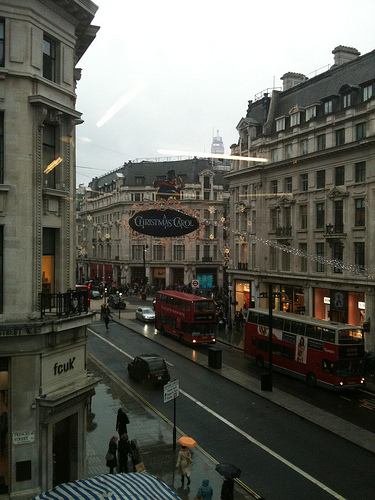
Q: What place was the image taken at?
A: It was taken at the street.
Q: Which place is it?
A: It is a street.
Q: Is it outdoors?
A: Yes, it is outdoors.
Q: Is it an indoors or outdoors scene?
A: It is outdoors.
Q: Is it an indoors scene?
A: No, it is outdoors.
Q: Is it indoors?
A: No, it is outdoors.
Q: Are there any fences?
A: No, there are no fences.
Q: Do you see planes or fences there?
A: No, there are no fences or planes.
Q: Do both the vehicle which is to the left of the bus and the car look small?
A: Yes, both the vehicle and the car are small.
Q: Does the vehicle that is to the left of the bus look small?
A: Yes, the vehicle is small.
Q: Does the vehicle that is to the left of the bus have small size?
A: Yes, the vehicle is small.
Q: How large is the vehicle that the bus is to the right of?
A: The vehicle is small.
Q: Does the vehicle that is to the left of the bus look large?
A: No, the vehicle is small.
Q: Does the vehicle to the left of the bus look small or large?
A: The vehicle is small.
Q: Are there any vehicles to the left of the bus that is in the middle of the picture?
A: Yes, there is a vehicle to the left of the bus.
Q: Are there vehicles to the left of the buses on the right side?
A: Yes, there is a vehicle to the left of the buses.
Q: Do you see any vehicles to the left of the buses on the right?
A: Yes, there is a vehicle to the left of the buses.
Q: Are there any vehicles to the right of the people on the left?
A: Yes, there is a vehicle to the right of the people.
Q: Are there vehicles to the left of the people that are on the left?
A: No, the vehicle is to the right of the people.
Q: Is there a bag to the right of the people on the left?
A: No, there is a vehicle to the right of the people.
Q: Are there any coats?
A: Yes, there is a coat.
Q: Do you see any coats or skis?
A: Yes, there is a coat.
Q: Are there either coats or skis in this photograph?
A: Yes, there is a coat.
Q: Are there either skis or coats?
A: Yes, there is a coat.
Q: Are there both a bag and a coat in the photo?
A: No, there is a coat but no bags.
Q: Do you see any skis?
A: No, there are no skis.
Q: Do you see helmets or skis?
A: No, there are no skis or helmets.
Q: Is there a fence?
A: No, there are no fences.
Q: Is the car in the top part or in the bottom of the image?
A: The car is in the bottom of the image.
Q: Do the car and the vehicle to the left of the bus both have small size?
A: Yes, both the car and the vehicle are small.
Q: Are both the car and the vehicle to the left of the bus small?
A: Yes, both the car and the vehicle are small.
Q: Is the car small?
A: Yes, the car is small.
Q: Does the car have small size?
A: Yes, the car is small.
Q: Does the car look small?
A: Yes, the car is small.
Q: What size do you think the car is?
A: The car is small.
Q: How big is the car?
A: The car is small.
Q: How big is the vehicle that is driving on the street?
A: The car is small.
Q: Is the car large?
A: No, the car is small.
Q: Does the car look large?
A: No, the car is small.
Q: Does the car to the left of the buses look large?
A: No, the car is small.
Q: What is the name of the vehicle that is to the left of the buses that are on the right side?
A: The vehicle is a car.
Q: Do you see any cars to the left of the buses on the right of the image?
A: Yes, there is a car to the left of the buses.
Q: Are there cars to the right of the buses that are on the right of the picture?
A: No, the car is to the left of the buses.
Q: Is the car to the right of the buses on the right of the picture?
A: No, the car is to the left of the buses.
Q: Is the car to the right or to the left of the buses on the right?
A: The car is to the left of the buses.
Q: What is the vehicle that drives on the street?
A: The vehicle is a car.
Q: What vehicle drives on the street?
A: The vehicle is a car.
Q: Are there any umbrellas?
A: Yes, there is an umbrella.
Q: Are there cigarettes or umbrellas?
A: Yes, there is an umbrella.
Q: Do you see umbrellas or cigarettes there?
A: Yes, there is an umbrella.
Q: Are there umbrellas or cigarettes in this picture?
A: Yes, there is an umbrella.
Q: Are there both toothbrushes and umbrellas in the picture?
A: No, there is an umbrella but no toothbrushes.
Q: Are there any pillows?
A: No, there are no pillows.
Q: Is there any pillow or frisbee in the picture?
A: No, there are no pillows or frisbees.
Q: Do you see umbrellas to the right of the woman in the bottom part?
A: Yes, there is an umbrella to the right of the woman.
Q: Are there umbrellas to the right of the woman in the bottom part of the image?
A: Yes, there is an umbrella to the right of the woman.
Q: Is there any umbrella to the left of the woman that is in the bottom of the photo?
A: No, the umbrella is to the right of the woman.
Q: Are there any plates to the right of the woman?
A: No, there is an umbrella to the right of the woman.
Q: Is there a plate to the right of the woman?
A: No, there is an umbrella to the right of the woman.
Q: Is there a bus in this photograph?
A: Yes, there is a bus.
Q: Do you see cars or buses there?
A: Yes, there is a bus.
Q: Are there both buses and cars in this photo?
A: Yes, there are both a bus and a car.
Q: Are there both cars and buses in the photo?
A: Yes, there are both a bus and a car.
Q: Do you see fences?
A: No, there are no fences.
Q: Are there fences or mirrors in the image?
A: No, there are no fences or mirrors.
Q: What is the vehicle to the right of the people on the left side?
A: The vehicle is a bus.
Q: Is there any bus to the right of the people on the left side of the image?
A: Yes, there is a bus to the right of the people.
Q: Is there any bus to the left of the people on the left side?
A: No, the bus is to the right of the people.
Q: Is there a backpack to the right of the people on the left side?
A: No, there is a bus to the right of the people.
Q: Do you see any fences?
A: No, there are no fences.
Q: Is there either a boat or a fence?
A: No, there are no fences or boats.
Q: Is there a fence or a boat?
A: No, there are no fences or boats.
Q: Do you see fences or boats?
A: No, there are no fences or boats.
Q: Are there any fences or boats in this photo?
A: No, there are no fences or boats.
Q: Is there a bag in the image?
A: No, there are no bags.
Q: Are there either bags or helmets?
A: No, there are no bags or helmets.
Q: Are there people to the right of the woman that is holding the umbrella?
A: Yes, there is a person to the right of the woman.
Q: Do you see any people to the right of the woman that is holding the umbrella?
A: Yes, there is a person to the right of the woman.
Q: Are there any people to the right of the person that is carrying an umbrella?
A: Yes, there is a person to the right of the woman.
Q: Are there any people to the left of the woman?
A: No, the person is to the right of the woman.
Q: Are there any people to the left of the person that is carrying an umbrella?
A: No, the person is to the right of the woman.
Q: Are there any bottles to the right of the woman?
A: No, there is a person to the right of the woman.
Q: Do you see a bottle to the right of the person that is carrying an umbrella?
A: No, there is a person to the right of the woman.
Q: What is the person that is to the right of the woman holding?
A: The person is holding the umbrella.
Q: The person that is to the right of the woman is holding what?
A: The person is holding the umbrella.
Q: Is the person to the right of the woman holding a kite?
A: No, the person is holding the umbrella.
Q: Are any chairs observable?
A: No, there are no chairs.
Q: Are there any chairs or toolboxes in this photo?
A: No, there are no chairs or toolboxes.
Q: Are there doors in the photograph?
A: Yes, there is a door.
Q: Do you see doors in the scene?
A: Yes, there is a door.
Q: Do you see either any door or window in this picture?
A: Yes, there is a door.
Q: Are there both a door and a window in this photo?
A: Yes, there are both a door and a window.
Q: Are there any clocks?
A: No, there are no clocks.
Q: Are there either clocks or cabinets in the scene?
A: No, there are no clocks or cabinets.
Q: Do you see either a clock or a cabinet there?
A: No, there are no clocks or cabinets.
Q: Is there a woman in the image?
A: Yes, there is a woman.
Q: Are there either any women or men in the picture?
A: Yes, there is a woman.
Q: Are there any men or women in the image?
A: Yes, there is a woman.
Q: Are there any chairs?
A: No, there are no chairs.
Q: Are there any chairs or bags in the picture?
A: No, there are no chairs or bags.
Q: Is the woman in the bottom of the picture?
A: Yes, the woman is in the bottom of the image.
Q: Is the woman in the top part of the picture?
A: No, the woman is in the bottom of the image.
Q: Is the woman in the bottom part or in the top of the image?
A: The woman is in the bottom of the image.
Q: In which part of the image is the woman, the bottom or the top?
A: The woman is in the bottom of the image.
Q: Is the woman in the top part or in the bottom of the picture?
A: The woman is in the bottom of the image.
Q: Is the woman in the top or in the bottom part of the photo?
A: The woman is in the bottom of the image.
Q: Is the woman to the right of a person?
A: No, the woman is to the left of a person.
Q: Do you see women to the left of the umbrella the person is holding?
A: Yes, there is a woman to the left of the umbrella.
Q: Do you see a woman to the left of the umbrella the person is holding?
A: Yes, there is a woman to the left of the umbrella.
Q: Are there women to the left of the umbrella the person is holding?
A: Yes, there is a woman to the left of the umbrella.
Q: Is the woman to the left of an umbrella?
A: Yes, the woman is to the left of an umbrella.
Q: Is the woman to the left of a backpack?
A: No, the woman is to the left of an umbrella.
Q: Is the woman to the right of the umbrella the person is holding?
A: No, the woman is to the left of the umbrella.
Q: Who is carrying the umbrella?
A: The woman is carrying the umbrella.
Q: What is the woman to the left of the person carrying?
A: The woman is carrying an umbrella.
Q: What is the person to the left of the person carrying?
A: The woman is carrying an umbrella.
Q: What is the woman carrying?
A: The woman is carrying an umbrella.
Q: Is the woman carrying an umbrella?
A: Yes, the woman is carrying an umbrella.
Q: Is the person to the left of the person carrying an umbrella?
A: Yes, the woman is carrying an umbrella.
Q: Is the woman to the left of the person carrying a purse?
A: No, the woman is carrying an umbrella.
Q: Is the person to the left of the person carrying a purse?
A: No, the woman is carrying an umbrella.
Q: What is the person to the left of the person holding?
A: The woman is holding the umbrella.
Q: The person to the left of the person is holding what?
A: The woman is holding the umbrella.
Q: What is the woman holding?
A: The woman is holding the umbrella.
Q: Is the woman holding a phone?
A: No, the woman is holding the umbrella.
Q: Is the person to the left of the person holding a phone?
A: No, the woman is holding the umbrella.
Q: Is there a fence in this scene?
A: No, there are no fences.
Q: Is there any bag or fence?
A: No, there are no fences or bags.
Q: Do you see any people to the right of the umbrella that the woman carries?
A: No, the people are to the left of the umbrella.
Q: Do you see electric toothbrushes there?
A: No, there are no electric toothbrushes.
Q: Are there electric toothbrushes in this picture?
A: No, there are no electric toothbrushes.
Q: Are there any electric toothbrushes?
A: No, there are no electric toothbrushes.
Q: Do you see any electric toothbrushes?
A: No, there are no electric toothbrushes.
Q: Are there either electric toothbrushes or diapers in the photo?
A: No, there are no electric toothbrushes or diapers.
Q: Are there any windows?
A: Yes, there are windows.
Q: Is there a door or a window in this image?
A: Yes, there are windows.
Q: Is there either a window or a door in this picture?
A: Yes, there are windows.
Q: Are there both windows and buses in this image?
A: Yes, there are both windows and a bus.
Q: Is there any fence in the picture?
A: No, there are no fences.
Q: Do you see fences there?
A: No, there are no fences.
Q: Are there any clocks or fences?
A: No, there are no fences or clocks.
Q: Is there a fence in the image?
A: No, there are no fences.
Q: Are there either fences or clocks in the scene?
A: No, there are no fences or clocks.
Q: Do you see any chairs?
A: No, there are no chairs.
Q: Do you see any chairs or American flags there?
A: No, there are no chairs or American flags.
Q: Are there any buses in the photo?
A: Yes, there are buses.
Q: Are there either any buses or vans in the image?
A: Yes, there are buses.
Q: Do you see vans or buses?
A: Yes, there are buses.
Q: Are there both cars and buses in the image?
A: Yes, there are both buses and a car.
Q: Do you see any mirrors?
A: No, there are no mirrors.